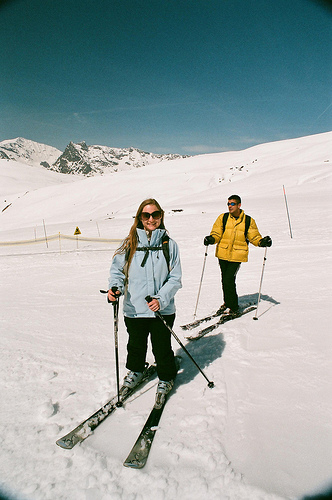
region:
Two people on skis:
[56, 177, 292, 486]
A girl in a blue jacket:
[64, 165, 209, 487]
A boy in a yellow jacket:
[186, 186, 273, 327]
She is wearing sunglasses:
[48, 176, 221, 283]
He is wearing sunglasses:
[198, 185, 273, 259]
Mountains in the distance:
[0, 104, 206, 194]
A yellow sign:
[22, 199, 102, 258]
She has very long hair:
[86, 187, 186, 370]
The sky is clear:
[11, 18, 274, 137]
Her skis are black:
[28, 192, 216, 496]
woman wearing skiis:
[113, 196, 186, 413]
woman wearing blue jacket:
[112, 196, 204, 401]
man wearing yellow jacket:
[214, 187, 258, 318]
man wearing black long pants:
[216, 257, 246, 322]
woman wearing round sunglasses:
[130, 199, 166, 229]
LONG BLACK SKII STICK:
[142, 286, 218, 391]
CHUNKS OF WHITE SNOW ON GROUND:
[24, 387, 60, 434]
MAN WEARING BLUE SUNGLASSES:
[194, 191, 275, 323]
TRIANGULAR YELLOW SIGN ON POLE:
[71, 222, 85, 238]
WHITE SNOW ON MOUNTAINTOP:
[56, 140, 175, 176]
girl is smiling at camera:
[136, 203, 172, 227]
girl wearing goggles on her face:
[134, 211, 169, 221]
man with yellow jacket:
[214, 192, 242, 262]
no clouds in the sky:
[8, 3, 325, 72]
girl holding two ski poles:
[90, 290, 235, 403]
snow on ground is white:
[189, 416, 267, 491]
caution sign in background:
[69, 217, 85, 240]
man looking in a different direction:
[221, 195, 234, 209]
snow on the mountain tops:
[0, 139, 172, 176]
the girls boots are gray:
[120, 372, 168, 400]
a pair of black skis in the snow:
[48, 394, 188, 482]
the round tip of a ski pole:
[210, 378, 215, 393]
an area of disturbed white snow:
[172, 427, 238, 494]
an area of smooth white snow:
[270, 419, 316, 495]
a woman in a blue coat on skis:
[114, 206, 188, 354]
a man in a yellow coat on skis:
[214, 195, 264, 316]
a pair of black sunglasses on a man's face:
[227, 199, 239, 208]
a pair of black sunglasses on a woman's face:
[138, 207, 164, 229]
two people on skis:
[86, 181, 278, 410]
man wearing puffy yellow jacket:
[201, 195, 267, 320]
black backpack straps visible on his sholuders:
[243, 212, 249, 242]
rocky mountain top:
[43, 142, 192, 178]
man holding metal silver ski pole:
[253, 245, 270, 322]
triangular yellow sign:
[73, 226, 80, 248]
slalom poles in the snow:
[281, 182, 295, 238]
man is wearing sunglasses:
[226, 201, 238, 206]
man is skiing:
[181, 195, 268, 340]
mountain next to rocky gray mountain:
[0, 136, 63, 170]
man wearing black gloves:
[257, 235, 271, 247]